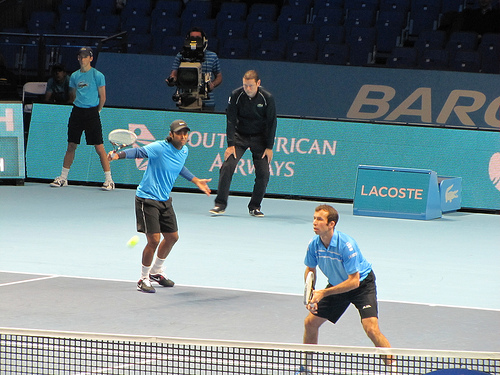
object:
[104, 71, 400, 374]
people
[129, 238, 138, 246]
ball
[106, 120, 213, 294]
man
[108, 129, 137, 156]
racket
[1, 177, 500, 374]
court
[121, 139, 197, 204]
shirt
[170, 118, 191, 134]
hat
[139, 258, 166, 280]
socks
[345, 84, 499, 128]
word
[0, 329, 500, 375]
net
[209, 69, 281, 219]
man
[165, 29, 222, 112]
man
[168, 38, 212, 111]
camera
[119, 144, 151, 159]
man's arms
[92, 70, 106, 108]
man's arms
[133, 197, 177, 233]
shorts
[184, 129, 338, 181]
sign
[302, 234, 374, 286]
shirt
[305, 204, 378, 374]
man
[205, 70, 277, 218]
referee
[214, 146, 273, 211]
pants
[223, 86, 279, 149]
shirt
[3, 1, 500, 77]
seats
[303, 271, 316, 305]
tennis rackets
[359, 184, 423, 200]
letters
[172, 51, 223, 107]
shirt